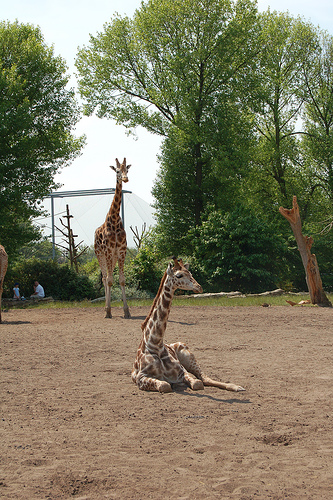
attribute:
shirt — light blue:
[11, 289, 26, 298]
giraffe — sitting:
[132, 255, 238, 394]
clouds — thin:
[52, 39, 145, 142]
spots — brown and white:
[160, 293, 170, 311]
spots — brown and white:
[156, 304, 168, 320]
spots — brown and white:
[177, 280, 181, 285]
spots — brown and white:
[112, 195, 120, 204]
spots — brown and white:
[107, 223, 112, 229]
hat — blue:
[13, 282, 18, 285]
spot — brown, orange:
[110, 224, 116, 231]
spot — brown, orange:
[111, 215, 117, 219]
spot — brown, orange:
[105, 221, 112, 227]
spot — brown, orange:
[115, 228, 121, 232]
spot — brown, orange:
[115, 222, 120, 228]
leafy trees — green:
[111, 0, 326, 293]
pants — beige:
[26, 288, 44, 305]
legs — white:
[164, 349, 247, 398]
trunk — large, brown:
[260, 193, 332, 313]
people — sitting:
[11, 280, 46, 301]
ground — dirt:
[1, 308, 332, 498]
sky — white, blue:
[0, 0, 330, 206]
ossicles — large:
[113, 155, 127, 165]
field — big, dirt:
[13, 301, 323, 497]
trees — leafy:
[125, 41, 269, 289]